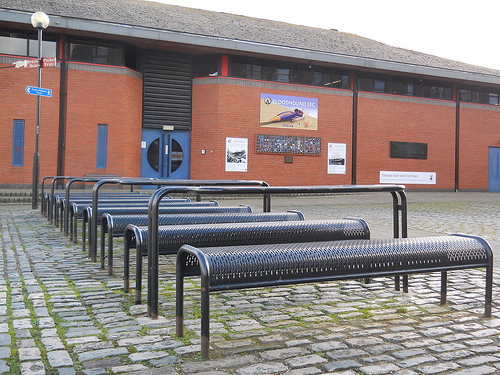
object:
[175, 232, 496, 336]
bench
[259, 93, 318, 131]
sign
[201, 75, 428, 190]
wall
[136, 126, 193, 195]
door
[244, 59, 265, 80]
windows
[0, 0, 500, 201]
building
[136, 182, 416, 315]
bar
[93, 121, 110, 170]
window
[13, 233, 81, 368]
ground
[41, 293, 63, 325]
grass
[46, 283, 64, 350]
crevice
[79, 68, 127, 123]
wall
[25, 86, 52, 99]
post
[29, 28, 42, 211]
pole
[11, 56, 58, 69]
sign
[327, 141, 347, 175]
sign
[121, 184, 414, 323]
metal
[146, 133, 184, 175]
windows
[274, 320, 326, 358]
stones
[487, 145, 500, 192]
shape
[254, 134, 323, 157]
mosaic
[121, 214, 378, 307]
benches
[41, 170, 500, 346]
lot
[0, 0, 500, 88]
roof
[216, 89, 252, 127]
brick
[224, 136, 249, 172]
poster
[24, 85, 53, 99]
street sign